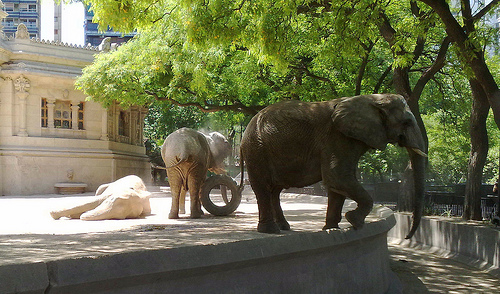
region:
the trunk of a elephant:
[389, 133, 466, 239]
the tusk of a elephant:
[407, 125, 445, 177]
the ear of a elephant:
[333, 85, 410, 158]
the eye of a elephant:
[387, 102, 445, 136]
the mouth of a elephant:
[374, 120, 439, 157]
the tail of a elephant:
[214, 130, 274, 185]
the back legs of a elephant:
[244, 125, 321, 255]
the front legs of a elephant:
[314, 160, 389, 250]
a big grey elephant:
[206, 68, 479, 236]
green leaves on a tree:
[176, 0, 328, 97]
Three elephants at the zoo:
[52, 92, 428, 241]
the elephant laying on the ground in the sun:
[52, 175, 151, 220]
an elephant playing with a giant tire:
[160, 130, 230, 217]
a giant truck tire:
[200, 174, 240, 213]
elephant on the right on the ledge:
[237, 94, 427, 237]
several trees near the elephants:
[86, 5, 498, 208]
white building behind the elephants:
[7, 34, 153, 189]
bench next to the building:
[53, 180, 87, 193]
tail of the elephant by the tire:
[147, 148, 188, 169]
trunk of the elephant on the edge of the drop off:
[406, 136, 428, 239]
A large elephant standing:
[239, 93, 426, 239]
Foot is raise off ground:
[346, 197, 372, 228]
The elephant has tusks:
[412, 148, 431, 158]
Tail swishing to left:
[147, 154, 186, 171]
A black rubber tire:
[201, 176, 240, 215]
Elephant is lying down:
[51, 174, 151, 220]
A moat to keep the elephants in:
[386, 206, 496, 291]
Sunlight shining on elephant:
[238, 92, 403, 147]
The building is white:
[1, 24, 149, 194]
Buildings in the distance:
[2, 3, 134, 45]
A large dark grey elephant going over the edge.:
[238, 95, 426, 239]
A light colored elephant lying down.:
[51, 175, 151, 222]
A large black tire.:
[197, 173, 241, 217]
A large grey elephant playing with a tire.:
[151, 125, 233, 217]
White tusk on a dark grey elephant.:
[408, 144, 430, 159]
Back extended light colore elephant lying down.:
[49, 196, 105, 218]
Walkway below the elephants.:
[384, 231, 499, 291]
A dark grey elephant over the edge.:
[401, 137, 428, 237]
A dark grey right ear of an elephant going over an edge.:
[332, 93, 386, 151]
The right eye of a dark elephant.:
[404, 117, 413, 127]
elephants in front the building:
[6, 5, 443, 282]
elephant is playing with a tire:
[153, 109, 246, 231]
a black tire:
[201, 171, 243, 218]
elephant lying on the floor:
[46, 162, 158, 231]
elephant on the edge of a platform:
[229, 82, 437, 263]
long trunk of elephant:
[400, 132, 430, 242]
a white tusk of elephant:
[408, 141, 433, 159]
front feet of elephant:
[316, 161, 376, 234]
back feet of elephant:
[247, 183, 292, 238]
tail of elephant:
[143, 152, 188, 171]